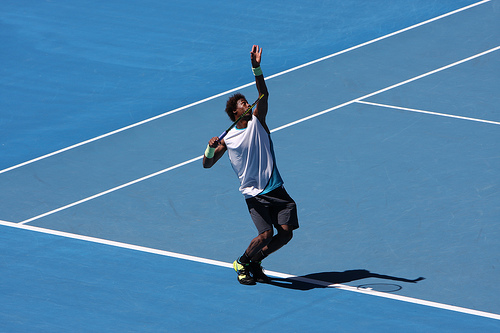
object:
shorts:
[245, 185, 300, 235]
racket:
[218, 94, 265, 141]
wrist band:
[250, 66, 262, 76]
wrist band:
[204, 145, 215, 159]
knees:
[264, 229, 273, 244]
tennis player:
[202, 45, 300, 285]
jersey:
[223, 114, 284, 200]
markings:
[3, 0, 498, 333]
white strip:
[356, 100, 500, 124]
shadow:
[268, 269, 427, 291]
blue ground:
[0, 1, 498, 331]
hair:
[224, 92, 245, 122]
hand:
[250, 44, 262, 67]